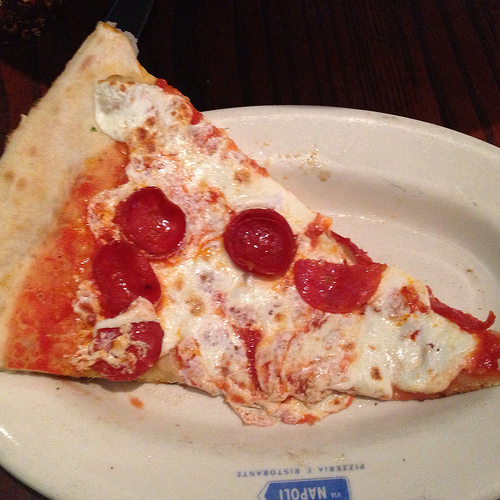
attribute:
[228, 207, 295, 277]
pepperoni — cooked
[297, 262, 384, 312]
pepperoni — cooked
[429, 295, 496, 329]
pepperoni — sliced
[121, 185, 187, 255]
pepperoni — cooked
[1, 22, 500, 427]
pizza — sliced, large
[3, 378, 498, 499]
plate — white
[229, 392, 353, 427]
cheese — melted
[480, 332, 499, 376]
sauce — red, tomato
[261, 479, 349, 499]
logo — blue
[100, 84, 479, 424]
cheese — melting, melted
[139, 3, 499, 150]
table — brown, dark